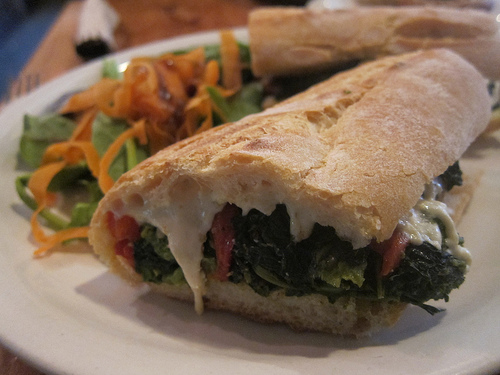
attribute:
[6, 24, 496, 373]
plate — white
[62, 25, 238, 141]
vegetable — orange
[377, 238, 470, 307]
vegetable — green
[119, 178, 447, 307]
sauce — white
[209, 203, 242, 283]
tomato — red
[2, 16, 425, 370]
plate — round, white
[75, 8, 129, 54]
napkin — white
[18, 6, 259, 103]
table — brown, wooden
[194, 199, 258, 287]
tomato — red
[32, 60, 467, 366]
plate — white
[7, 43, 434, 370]
plate — white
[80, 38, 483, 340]
sandwich — half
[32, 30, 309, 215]
salad — green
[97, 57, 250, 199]
carrots — orange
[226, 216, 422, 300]
broccoli — green